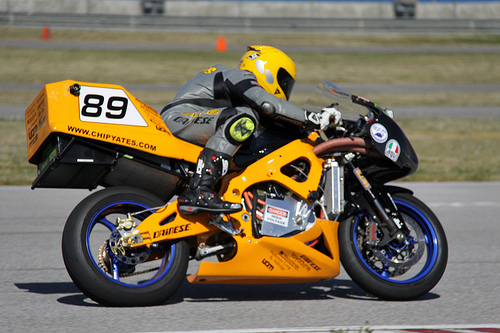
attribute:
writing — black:
[79, 89, 129, 120]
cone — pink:
[215, 30, 225, 53]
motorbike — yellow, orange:
[26, 67, 454, 309]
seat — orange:
[20, 79, 210, 171]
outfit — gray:
[157, 60, 320, 165]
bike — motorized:
[20, 71, 450, 311]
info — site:
[65, 120, 162, 157]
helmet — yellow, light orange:
[235, 35, 302, 106]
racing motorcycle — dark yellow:
[16, 70, 453, 306]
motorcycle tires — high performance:
[56, 183, 451, 304]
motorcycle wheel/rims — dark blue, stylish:
[58, 186, 452, 300]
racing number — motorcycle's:
[77, 82, 136, 131]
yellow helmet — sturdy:
[240, 41, 299, 99]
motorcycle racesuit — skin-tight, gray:
[164, 69, 339, 218]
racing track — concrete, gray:
[0, 183, 481, 331]